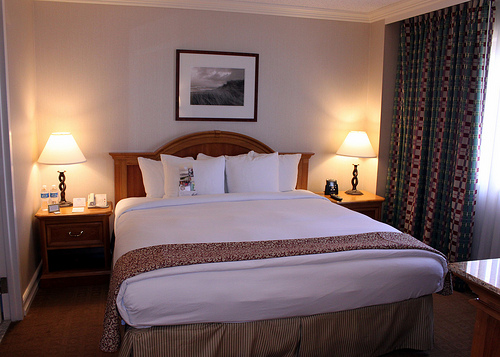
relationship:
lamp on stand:
[37, 129, 87, 208] [36, 203, 114, 284]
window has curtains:
[377, 3, 500, 302] [384, 1, 499, 265]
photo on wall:
[175, 48, 261, 123] [3, 1, 371, 297]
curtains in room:
[384, 1, 499, 265] [0, 1, 498, 356]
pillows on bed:
[135, 148, 302, 199] [102, 127, 454, 357]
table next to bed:
[328, 192, 386, 224] [102, 127, 454, 357]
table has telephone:
[328, 192, 386, 224] [321, 178, 341, 196]